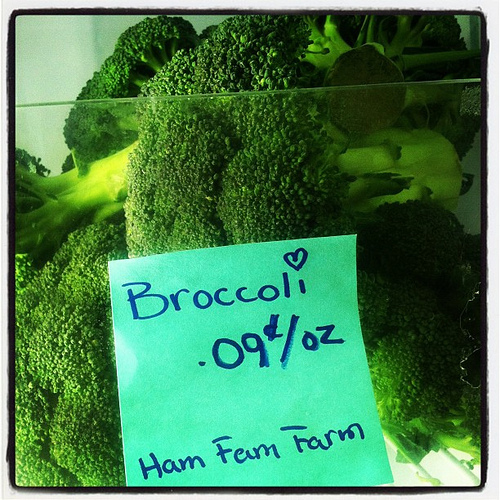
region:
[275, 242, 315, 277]
Blue heart drawn on paper.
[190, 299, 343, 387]
Price of item on paper.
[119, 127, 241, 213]
Broccoli being sold.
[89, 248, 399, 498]
Blue paper on broccoli.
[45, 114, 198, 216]
Shade of dark and light green on broccoli.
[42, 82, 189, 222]
Plastic divider in the broccoli.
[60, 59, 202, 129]
Edge of straight line on clear panel.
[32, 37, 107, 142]
White wall in the background.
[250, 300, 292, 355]
Cent sign on the blue paper.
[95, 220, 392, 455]
Blue sticky note paper.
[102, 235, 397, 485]
a small note pricing brocolli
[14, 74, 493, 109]
edge of a pane of glass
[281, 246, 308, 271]
blue heart drawn on paper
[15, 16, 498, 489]
brocolli behind a pane of glass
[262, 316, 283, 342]
cent sign written on paper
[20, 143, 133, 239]
the stalk of a piece of brocolli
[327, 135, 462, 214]
the stalk of a piece of brocolli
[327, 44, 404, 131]
the base of a stalk of brocolli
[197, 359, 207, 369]
a period written on paper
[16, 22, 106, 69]
a patch of white wall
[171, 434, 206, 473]
part of a letter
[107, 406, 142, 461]
edge of a card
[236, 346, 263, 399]
part of a number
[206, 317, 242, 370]
part of a number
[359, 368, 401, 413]
edge of a card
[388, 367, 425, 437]
part of a plant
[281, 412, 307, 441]
part of a letter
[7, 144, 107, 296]
Broccoli stem and head.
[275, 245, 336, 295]
Heart used as dot for i.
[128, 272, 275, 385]
Blue writing on paper.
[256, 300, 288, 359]
Cent sign on paper.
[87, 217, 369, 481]
Blue sticky note stuck on clear plastic.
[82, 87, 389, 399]
Plexiglass holding in broccoli.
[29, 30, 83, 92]
White wall in background.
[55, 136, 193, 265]
Dark and light green colors on broccoli.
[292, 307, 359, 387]
Weight abbreviation on paper.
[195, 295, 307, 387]
Price of broccoli on paper.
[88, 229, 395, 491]
the note is blue paper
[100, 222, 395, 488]
the note is on the broccoli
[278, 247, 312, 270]
the I is dotted with a heart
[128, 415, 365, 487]
the broccoli is from Ham Fam Farm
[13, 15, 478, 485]
the Broccoli is very green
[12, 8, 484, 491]
the Broccoli is raw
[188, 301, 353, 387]
the Broccoli is .09 cents an ounce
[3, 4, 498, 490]
the broccoli is cut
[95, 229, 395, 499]
the note is written with marker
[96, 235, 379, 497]
the marker the note was written with has blue ink